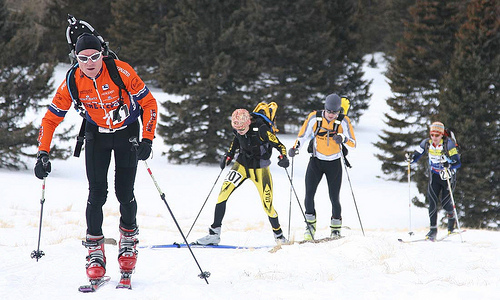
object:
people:
[404, 120, 465, 238]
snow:
[1, 52, 500, 297]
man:
[35, 33, 164, 278]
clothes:
[35, 58, 160, 154]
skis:
[112, 222, 143, 293]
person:
[288, 92, 358, 242]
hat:
[72, 32, 100, 55]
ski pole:
[129, 135, 212, 287]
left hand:
[131, 139, 152, 161]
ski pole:
[29, 156, 52, 263]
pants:
[210, 159, 283, 233]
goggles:
[74, 49, 104, 67]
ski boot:
[83, 234, 109, 280]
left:
[85, 234, 106, 280]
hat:
[321, 93, 345, 111]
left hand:
[333, 133, 348, 146]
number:
[226, 169, 238, 181]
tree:
[0, 0, 76, 170]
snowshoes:
[256, 101, 282, 133]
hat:
[226, 108, 252, 129]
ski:
[149, 243, 247, 249]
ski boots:
[119, 225, 142, 275]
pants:
[304, 156, 344, 223]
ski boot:
[197, 224, 225, 245]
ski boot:
[303, 213, 319, 242]